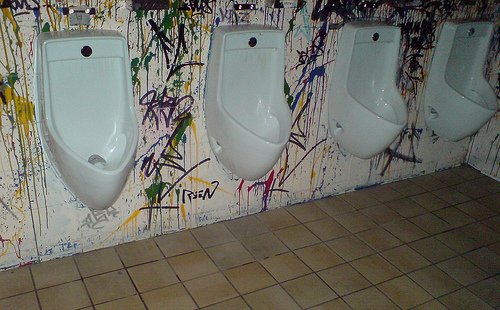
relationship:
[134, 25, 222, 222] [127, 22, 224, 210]
graffiti on restroom wall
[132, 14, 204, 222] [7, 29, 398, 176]
paint on wall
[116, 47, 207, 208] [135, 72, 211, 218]
scribble on wall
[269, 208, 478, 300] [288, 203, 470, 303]
shapes on floor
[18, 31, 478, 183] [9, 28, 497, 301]
wall in restroom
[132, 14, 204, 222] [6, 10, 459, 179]
paint on wall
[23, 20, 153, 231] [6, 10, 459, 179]
toilet on wall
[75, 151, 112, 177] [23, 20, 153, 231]
plastic pad in toilet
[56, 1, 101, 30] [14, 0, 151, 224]
sheet over urinal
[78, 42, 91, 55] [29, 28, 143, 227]
circle on urinal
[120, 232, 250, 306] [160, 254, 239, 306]
tile on floor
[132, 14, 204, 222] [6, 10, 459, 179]
paint dripping down wall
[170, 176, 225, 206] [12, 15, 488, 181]
letters on wall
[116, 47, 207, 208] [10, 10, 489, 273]
scribble on wall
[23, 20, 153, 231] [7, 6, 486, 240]
toilet on wall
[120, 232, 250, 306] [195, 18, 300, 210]
tile below toilet